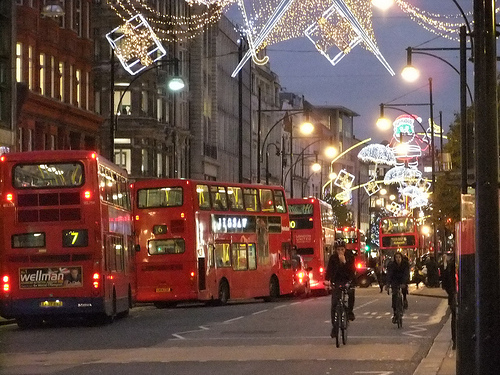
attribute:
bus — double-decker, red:
[0, 147, 135, 324]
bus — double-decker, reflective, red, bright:
[128, 178, 295, 304]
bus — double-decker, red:
[287, 194, 336, 292]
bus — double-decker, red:
[380, 215, 438, 273]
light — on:
[400, 46, 421, 87]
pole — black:
[459, 26, 469, 199]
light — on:
[377, 103, 391, 133]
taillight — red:
[92, 263, 103, 294]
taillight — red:
[2, 270, 12, 301]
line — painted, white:
[223, 314, 245, 324]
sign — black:
[208, 213, 283, 232]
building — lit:
[13, 1, 101, 153]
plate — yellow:
[40, 300, 65, 307]